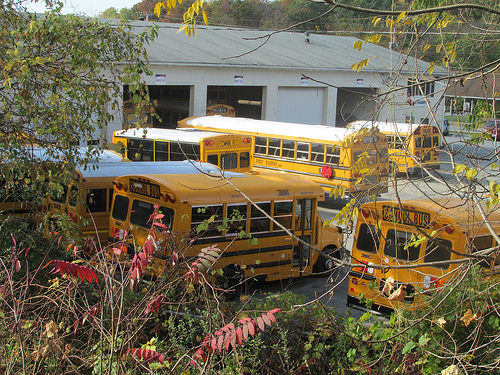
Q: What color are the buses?
A: Yellow.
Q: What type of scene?
A: Outdoor.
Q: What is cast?
A: Shadow.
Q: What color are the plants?
A: Green.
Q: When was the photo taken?
A: Daytime.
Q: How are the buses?
A: Parked.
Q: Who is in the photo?
A: No one.